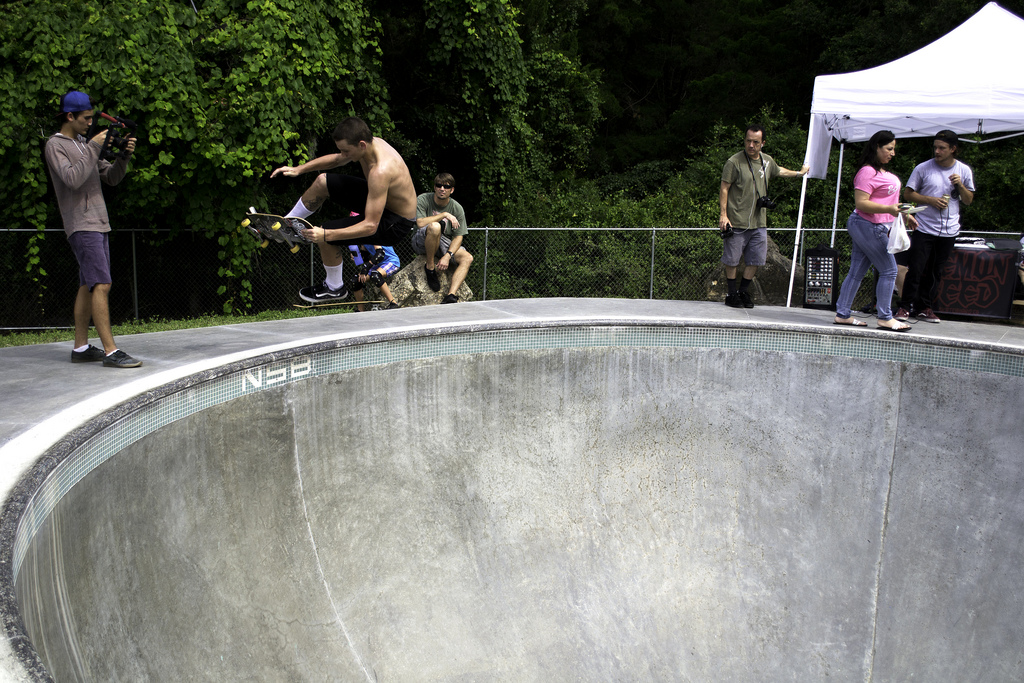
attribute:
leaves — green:
[135, 87, 213, 172]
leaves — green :
[221, 35, 304, 74]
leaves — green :
[193, 59, 308, 133]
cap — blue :
[53, 73, 114, 119]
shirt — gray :
[50, 136, 130, 249]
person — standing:
[713, 117, 813, 312]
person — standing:
[825, 102, 936, 362]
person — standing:
[26, 74, 176, 379]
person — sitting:
[347, 126, 536, 334]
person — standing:
[697, 128, 791, 297]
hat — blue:
[53, 66, 147, 140]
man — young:
[32, 110, 149, 391]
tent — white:
[747, 107, 1015, 136]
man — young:
[242, 209, 418, 296]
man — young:
[423, 215, 482, 295]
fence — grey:
[168, 226, 238, 335]